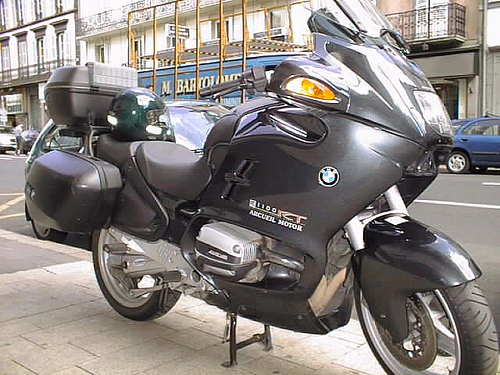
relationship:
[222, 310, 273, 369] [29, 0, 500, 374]
kickstand on motorcycle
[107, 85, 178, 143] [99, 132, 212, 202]
helmet on seat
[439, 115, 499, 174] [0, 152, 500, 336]
car on road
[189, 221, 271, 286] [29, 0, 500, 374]
engine of motorcycle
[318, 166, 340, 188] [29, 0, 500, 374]
insignia on motorcycle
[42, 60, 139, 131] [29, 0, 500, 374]
storage compartment on motorcycle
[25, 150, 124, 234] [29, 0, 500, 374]
storage compartment on motorcycle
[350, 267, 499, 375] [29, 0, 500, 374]
wheel of motorcycle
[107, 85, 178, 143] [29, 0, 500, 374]
helmet sitting on motorcycle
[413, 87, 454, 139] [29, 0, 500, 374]
headlight of motorcycle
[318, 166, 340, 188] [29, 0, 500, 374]
insignia of motorcycle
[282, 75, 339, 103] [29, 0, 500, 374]
light of motorcycle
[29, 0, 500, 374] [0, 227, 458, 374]
motorcycle parked on sidewalk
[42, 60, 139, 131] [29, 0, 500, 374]
storage compartment attached to motorcycle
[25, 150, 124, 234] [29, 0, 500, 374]
storage compartment attached to motorcycle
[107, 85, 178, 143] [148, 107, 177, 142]
helmet has face mask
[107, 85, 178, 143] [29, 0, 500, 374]
helmet on motorcycle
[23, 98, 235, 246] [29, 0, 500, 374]
car behind motorcycle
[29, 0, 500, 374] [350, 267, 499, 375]
motorcycle has wheel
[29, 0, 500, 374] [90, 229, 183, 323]
motorcycle has wheel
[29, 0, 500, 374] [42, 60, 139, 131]
motorcycle has storage compartment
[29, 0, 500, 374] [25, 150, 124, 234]
motorcycle has storage compartment